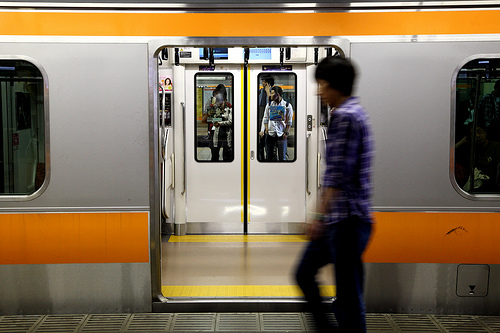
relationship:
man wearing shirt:
[296, 55, 374, 332] [313, 104, 372, 224]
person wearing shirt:
[262, 79, 293, 158] [261, 95, 291, 135]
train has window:
[2, 10, 492, 312] [0, 56, 51, 204]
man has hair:
[296, 55, 374, 332] [315, 55, 355, 93]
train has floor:
[2, 10, 492, 312] [160, 227, 334, 297]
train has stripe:
[2, 10, 492, 312] [1, 11, 500, 34]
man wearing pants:
[296, 55, 374, 332] [292, 202, 371, 331]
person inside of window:
[207, 80, 238, 161] [0, 56, 51, 204]